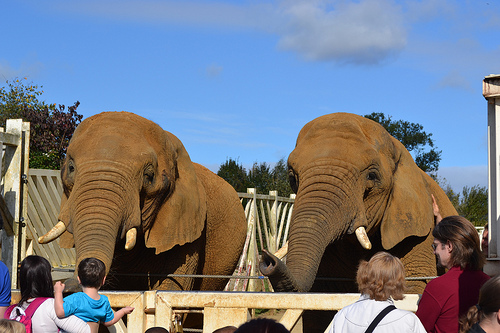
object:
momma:
[1, 251, 108, 333]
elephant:
[252, 109, 465, 296]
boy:
[52, 256, 135, 328]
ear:
[143, 144, 211, 256]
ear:
[380, 135, 433, 251]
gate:
[0, 288, 427, 333]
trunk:
[61, 196, 125, 293]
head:
[14, 254, 57, 300]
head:
[74, 254, 110, 292]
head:
[354, 250, 409, 304]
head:
[431, 214, 490, 273]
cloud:
[259, 4, 439, 97]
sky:
[2, 0, 500, 207]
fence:
[25, 167, 297, 294]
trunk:
[257, 159, 370, 294]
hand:
[120, 304, 137, 316]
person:
[320, 249, 435, 333]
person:
[413, 213, 498, 333]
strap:
[362, 304, 398, 333]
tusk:
[123, 226, 139, 252]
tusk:
[35, 220, 68, 246]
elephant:
[35, 107, 252, 295]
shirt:
[60, 289, 116, 325]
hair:
[355, 250, 410, 302]